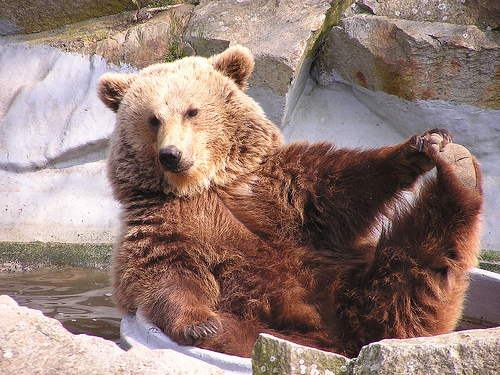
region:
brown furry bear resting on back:
[93, 42, 487, 342]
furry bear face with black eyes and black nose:
[95, 35, 277, 192]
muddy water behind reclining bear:
[1, 256, 499, 343]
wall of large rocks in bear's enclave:
[8, 0, 499, 245]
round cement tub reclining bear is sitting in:
[114, 243, 498, 367]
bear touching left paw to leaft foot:
[297, 109, 498, 331]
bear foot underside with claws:
[428, 123, 488, 219]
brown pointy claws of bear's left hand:
[181, 318, 226, 341]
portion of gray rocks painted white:
[0, 40, 498, 242]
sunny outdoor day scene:
[6, 0, 496, 363]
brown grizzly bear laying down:
[64, 40, 484, 342]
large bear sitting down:
[72, 48, 458, 363]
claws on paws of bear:
[192, 314, 217, 337]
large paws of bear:
[175, 308, 216, 342]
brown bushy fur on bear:
[184, 180, 309, 287]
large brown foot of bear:
[440, 145, 468, 180]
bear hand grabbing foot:
[408, 125, 471, 180]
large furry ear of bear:
[215, 33, 257, 85]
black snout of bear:
[167, 145, 179, 167]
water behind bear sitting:
[17, 254, 92, 316]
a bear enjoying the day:
[97, 46, 482, 358]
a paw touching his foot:
[404, 128, 488, 208]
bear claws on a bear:
[179, 322, 220, 339]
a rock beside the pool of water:
[251, 327, 354, 374]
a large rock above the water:
[310, 14, 498, 106]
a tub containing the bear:
[118, 263, 497, 373]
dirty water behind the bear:
[0, 265, 130, 350]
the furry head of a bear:
[99, 43, 286, 196]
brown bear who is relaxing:
[96, 44, 486, 358]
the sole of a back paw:
[432, 136, 479, 192]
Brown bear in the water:
[83, 35, 478, 355]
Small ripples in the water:
[5, 263, 28, 295]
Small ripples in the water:
[28, 261, 48, 293]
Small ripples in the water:
[49, 264, 101, 306]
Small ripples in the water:
[90, 262, 119, 311]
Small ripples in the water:
[50, 294, 115, 343]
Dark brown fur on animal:
[127, 211, 174, 246]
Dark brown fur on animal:
[153, 243, 213, 290]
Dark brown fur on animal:
[188, 215, 330, 327]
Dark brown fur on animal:
[268, 176, 341, 241]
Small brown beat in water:
[78, 29, 498, 336]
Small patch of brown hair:
[425, 195, 471, 227]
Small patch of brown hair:
[420, 241, 454, 300]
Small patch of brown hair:
[380, 238, 445, 292]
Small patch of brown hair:
[363, 147, 411, 176]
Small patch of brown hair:
[330, 145, 370, 193]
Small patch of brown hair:
[307, 164, 354, 211]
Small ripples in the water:
[35, 261, 61, 288]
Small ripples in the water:
[41, 288, 82, 331]